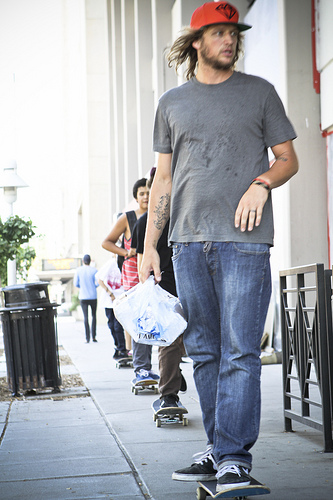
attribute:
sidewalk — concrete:
[4, 319, 332, 497]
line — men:
[96, 0, 331, 479]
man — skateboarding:
[128, 161, 234, 428]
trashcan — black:
[2, 279, 69, 409]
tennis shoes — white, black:
[166, 448, 261, 490]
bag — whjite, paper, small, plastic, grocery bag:
[111, 271, 190, 355]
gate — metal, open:
[279, 264, 329, 450]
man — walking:
[74, 254, 105, 341]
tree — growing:
[2, 214, 44, 288]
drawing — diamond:
[217, 1, 240, 22]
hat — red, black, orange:
[186, 0, 250, 40]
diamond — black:
[215, 2, 240, 23]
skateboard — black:
[192, 464, 269, 498]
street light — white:
[3, 157, 29, 283]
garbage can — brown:
[2, 282, 64, 395]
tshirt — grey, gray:
[150, 69, 305, 253]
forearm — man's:
[150, 176, 175, 247]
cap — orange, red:
[185, 1, 253, 39]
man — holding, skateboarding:
[137, 0, 303, 493]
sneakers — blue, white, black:
[170, 449, 254, 491]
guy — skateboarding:
[128, 160, 196, 430]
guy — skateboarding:
[100, 177, 160, 398]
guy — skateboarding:
[98, 249, 136, 369]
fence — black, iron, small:
[272, 258, 333, 452]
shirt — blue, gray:
[153, 72, 302, 247]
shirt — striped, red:
[121, 207, 154, 290]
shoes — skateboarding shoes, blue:
[133, 366, 164, 383]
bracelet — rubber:
[250, 183, 271, 191]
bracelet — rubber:
[255, 175, 277, 188]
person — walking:
[73, 247, 108, 352]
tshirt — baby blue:
[74, 262, 99, 302]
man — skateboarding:
[99, 173, 177, 397]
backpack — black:
[115, 210, 153, 276]